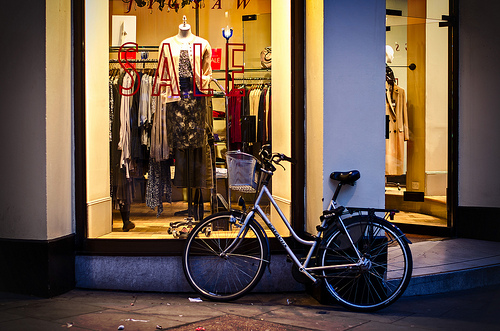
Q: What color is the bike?
A: White.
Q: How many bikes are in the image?
A: One.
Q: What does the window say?
A: SALE.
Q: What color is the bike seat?
A: Black.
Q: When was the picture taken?
A: During the day.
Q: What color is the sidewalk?
A: Brown.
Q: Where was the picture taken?
A: By the clothing shop.